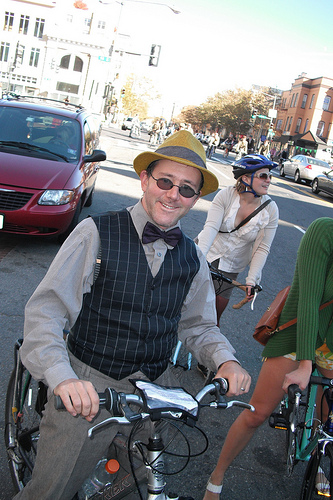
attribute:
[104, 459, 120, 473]
cap — orange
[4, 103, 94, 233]
minivan — red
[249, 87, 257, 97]
light — white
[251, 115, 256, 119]
light — green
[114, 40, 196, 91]
light — traffic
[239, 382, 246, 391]
wedding band — man's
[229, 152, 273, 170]
helmet — blue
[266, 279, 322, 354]
bag — brown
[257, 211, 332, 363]
sweater — long sleeved, green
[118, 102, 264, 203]
hat — yellow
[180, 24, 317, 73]
sky — blue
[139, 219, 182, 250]
bowtie — brown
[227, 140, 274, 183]
helmet — blue and black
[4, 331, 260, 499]
mountain bike — grey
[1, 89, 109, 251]
maroon car — stopped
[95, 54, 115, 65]
sign — green and white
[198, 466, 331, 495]
sandle — white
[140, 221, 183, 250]
bow tie — black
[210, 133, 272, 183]
helmet — blue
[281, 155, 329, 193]
car — white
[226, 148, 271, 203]
helmet — blue, black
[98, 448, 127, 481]
lid — orange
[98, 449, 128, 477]
cap — orange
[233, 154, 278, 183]
helmet — blue, black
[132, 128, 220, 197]
hat — yellow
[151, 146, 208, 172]
trim — gray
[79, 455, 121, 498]
bottle — plastic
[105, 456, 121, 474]
top — orange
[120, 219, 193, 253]
bow tie — black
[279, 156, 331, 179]
car — large, gray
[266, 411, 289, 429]
pedal — black and yellow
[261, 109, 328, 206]
car — silver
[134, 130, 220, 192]
hat — black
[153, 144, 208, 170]
band — grey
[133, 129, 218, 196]
man's hat — yellow